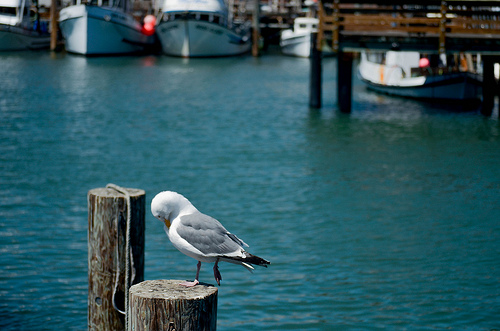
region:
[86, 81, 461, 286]
the water is blue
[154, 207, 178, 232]
the beak is orange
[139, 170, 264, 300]
the bird is white and grey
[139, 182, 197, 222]
the head is white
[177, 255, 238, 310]
one foot is up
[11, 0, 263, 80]
the boats are parked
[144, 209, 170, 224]
the eye is a black dot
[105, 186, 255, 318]
bird is standing on a pole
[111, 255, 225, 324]
the pole is made of wood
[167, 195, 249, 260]
the wings are grey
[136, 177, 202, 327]
The bird is on a wooden post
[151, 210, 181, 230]
The bird's beak is orange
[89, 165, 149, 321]
The wooden post has a rope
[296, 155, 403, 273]
The water is calm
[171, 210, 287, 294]
The bird has gray wings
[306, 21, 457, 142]
The dock is wooden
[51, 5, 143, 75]
The boat is white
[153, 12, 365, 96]
The boats are not running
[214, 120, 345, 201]
The water is blue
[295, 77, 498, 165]
The dock is in the water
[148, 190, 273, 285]
Gray and white sea gul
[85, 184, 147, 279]
Part of wooden post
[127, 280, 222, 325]
Part of wooden post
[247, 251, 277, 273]
Tail of gray seagull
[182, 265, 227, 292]
Feet of gray seagull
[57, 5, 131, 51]
Blue boat docked in harbor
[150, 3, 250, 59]
Green boat docked in harbor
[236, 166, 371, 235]
Calm blue water in harbor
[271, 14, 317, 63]
Small boat docked in harbor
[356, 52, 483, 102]
Small boat docked in harbor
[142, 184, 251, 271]
gray and white bird on post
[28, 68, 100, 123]
dark green water in river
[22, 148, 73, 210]
dark green water in river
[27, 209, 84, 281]
dark green water in river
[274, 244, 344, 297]
dark green water in river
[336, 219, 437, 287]
dark green water in river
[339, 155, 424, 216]
dark green water in river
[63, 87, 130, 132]
dark green water in river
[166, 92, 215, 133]
dark green water in river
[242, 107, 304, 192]
dark green water in river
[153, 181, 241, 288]
white and gray seagull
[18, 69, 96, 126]
greenish blue water in river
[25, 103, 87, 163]
greenish blue water in river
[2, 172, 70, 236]
greenish blue water in river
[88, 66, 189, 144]
greenish blue water in river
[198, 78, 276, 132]
greenish blue water in river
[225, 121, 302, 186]
greenish blue water in river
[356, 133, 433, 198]
greenish blue water in river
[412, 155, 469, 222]
greenish blue water in river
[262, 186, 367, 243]
greenish blue water in river